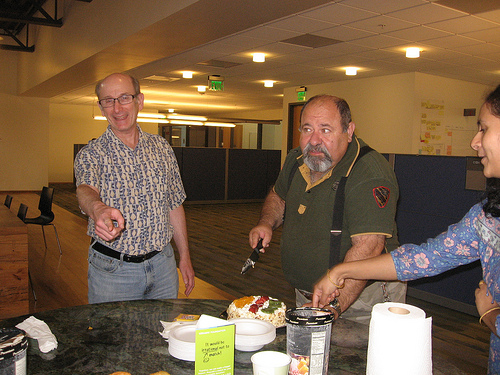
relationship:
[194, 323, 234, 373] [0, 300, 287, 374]
green sign on table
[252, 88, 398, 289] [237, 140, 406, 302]
man wearing suspenders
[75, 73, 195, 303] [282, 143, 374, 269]
man wearing suspenders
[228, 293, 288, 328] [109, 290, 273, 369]
cake sitting on table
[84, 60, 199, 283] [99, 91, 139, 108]
man with glasses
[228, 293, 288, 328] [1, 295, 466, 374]
cake on table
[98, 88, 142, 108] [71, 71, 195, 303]
glasses on man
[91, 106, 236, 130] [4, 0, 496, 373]
flourescent light in room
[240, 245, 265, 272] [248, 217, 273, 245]
knife on hand